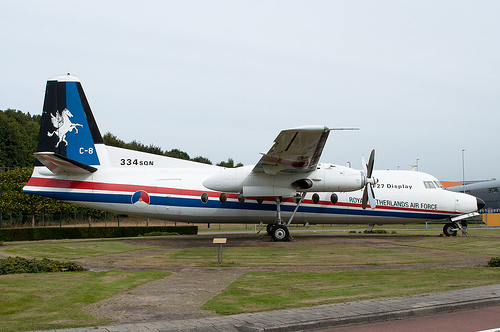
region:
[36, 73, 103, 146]
part of large airplane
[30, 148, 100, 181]
part of large airplane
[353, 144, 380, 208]
part of large airplane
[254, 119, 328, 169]
part of large airplane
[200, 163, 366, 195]
part of large airplane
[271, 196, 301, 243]
part of large airplane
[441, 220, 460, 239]
part of large airplane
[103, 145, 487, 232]
part of large airplane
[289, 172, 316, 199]
part of large airplane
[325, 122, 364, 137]
part of large airplane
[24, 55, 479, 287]
Airplane on a the ground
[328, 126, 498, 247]
Airplane on a the ground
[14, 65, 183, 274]
Airplane on a the ground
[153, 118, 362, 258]
Airplane on a the ground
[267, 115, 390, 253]
Airplane on a the ground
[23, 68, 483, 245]
Airplane on a the ground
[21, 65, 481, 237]
Airplane on a the ground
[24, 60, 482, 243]
Airplane on a the ground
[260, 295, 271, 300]
Part of the green grass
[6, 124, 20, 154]
Part of the green trees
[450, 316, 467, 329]
Part of the road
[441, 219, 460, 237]
The front wheel of the airplane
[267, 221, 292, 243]
The back wheel of the airplane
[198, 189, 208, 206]
A window on the airplane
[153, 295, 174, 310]
Part of the sidewalk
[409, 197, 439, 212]
Letters on the airplane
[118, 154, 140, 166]
Numbers on the airplane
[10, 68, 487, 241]
a plane on a landing strip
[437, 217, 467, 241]
front wheel of plane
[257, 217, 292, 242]
back wheels of plane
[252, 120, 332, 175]
right wing of plane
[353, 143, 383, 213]
propeller in front an engine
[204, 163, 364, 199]
the engine of plane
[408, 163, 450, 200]
the cockpit of plane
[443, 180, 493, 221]
tip of nose is black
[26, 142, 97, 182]
horizontal stabilizer of plane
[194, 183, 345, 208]
windows of plane are round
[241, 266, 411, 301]
The grass is short and green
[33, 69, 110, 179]
The back tail of the airplane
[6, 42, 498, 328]
The airplane is on the ground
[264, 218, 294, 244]
The back wheel of the plane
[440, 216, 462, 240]
The front wheel of the plane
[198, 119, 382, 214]
The side wing of the airplane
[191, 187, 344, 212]
The windows on the plane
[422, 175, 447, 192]
The windshield of the airplane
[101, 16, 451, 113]
The sky is smoky and light blue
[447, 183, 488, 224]
The nose of the airplane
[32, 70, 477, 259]
Large plane on the ground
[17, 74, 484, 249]
White plane on the ground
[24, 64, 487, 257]
Large white plane on the ground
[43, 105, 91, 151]
Logo on the plane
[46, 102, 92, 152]
Logo on the tail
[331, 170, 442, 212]
Writing on the plane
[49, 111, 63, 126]
wings are on the horse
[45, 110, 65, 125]
the wings are white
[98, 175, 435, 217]
the stripes on the plane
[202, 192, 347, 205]
windows on the plane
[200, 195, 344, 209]
the windows are dark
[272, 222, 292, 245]
the wheel is black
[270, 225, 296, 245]
the wheel is in the grass